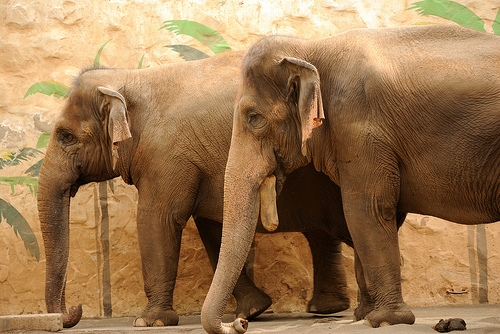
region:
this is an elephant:
[238, 36, 497, 171]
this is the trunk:
[204, 155, 244, 330]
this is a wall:
[11, 15, 84, 74]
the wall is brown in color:
[11, 16, 115, 73]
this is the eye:
[243, 111, 267, 121]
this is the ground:
[266, 309, 305, 331]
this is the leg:
[336, 158, 400, 313]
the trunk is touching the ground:
[198, 295, 265, 331]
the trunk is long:
[32, 192, 83, 284]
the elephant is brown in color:
[151, 81, 214, 157]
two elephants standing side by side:
[10, 23, 497, 330]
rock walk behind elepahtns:
[8, 15, 498, 299]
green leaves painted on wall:
[23, 16, 490, 181]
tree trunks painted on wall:
[88, 188, 493, 331]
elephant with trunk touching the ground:
[195, 165, 271, 332]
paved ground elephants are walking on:
[37, 312, 499, 331]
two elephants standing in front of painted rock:
[14, 42, 493, 314]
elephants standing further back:
[195, 35, 499, 329]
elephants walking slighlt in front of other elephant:
[24, 67, 245, 313]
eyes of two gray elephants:
[47, 103, 272, 165]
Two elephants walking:
[21, 7, 498, 332]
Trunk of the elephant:
[33, 195, 97, 332]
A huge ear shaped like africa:
[279, 53, 333, 163]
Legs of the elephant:
[133, 201, 445, 332]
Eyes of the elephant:
[56, 105, 291, 155]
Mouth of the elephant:
[267, 162, 298, 219]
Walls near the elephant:
[18, 5, 334, 32]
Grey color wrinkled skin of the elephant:
[167, 83, 453, 178]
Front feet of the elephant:
[120, 300, 185, 332]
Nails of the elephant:
[130, 316, 162, 332]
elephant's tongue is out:
[255, 168, 284, 233]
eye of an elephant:
[246, 108, 261, 131]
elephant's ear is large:
[95, 82, 132, 170]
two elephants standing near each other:
[38, 20, 497, 330]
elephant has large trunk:
[36, 165, 84, 325]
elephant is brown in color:
[197, 30, 498, 331]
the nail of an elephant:
[133, 315, 146, 325]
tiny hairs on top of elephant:
[72, 66, 127, 73]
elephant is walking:
[38, 54, 333, 329]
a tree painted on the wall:
[36, 52, 150, 314]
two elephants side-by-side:
[25, 11, 496, 331]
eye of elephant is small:
[237, 103, 271, 133]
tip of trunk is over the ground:
[190, 230, 260, 330]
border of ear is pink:
[287, 58, 331, 169]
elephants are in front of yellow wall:
[9, 8, 497, 317]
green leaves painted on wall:
[31, 11, 231, 57]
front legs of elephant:
[332, 191, 425, 312]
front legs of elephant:
[116, 200, 273, 330]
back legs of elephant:
[301, 234, 370, 322]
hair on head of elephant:
[63, 57, 124, 94]